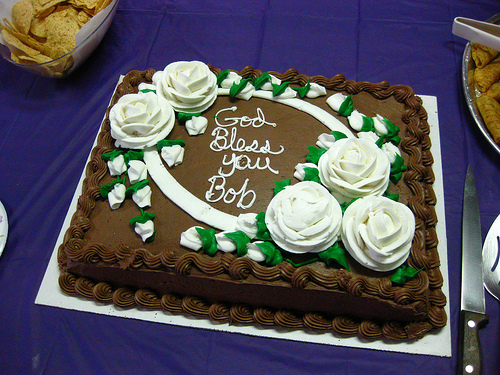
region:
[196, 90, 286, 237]
letters on cake are white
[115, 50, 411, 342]
white roses on cake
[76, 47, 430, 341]
cake made of chocolate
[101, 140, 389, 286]
green leaves on cake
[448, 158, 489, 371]
knife laying next to cake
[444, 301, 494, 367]
knife handle is black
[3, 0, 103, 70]
chips in glass bowl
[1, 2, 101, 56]
paper is under chips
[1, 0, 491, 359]
the table cloth is blue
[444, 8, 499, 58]
tongs in the pan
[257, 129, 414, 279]
large white frosting roses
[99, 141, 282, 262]
white frosting rose buds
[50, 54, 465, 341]
a chocolate sheet cake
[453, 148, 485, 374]
wood handle stainless steel knife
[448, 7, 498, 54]
the handle end of tongs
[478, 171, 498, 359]
part of a cake server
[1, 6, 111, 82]
bowl of nacho chips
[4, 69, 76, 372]
bluish puple table cloth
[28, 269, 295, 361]
white cardboard holding the cake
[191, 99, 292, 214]
message written in white icing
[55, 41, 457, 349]
rectangular cake decorated with white flowers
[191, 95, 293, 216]
"God Bless you Bob" is written on the cake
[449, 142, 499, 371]
pointy metal knife with a wooden handle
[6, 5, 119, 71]
bowl of tortilla chips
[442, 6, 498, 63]
end of a pair of tongs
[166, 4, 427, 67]
blue paper table cloth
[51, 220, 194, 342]
chocolate icing on the cake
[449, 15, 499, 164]
food in circular metal tin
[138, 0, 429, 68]
creases in the table cloth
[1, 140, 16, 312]
edge of a paper plate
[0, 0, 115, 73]
dish with chips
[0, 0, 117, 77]
glass dish with chips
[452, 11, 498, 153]
silver platter with food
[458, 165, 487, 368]
long knife to the right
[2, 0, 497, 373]
royal blue table cloth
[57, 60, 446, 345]
brown chocolate cake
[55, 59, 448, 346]
chocolate cake with brown, green and white icing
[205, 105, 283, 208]
white icing writing on the cake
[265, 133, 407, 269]
group of three white flower petals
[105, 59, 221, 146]
group of two white icing flower petals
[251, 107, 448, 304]
white flowers made of frosting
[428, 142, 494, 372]
a black knife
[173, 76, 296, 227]
God bless you Bob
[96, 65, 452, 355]
a cake with God bless you Bob written on it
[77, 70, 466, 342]
a chocolate frosted cake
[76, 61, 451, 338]
a cake with white flowers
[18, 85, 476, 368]
a blue table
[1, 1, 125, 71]
a bowl of chips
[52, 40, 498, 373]
a cake on a blue table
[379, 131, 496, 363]
a knife on a blue table